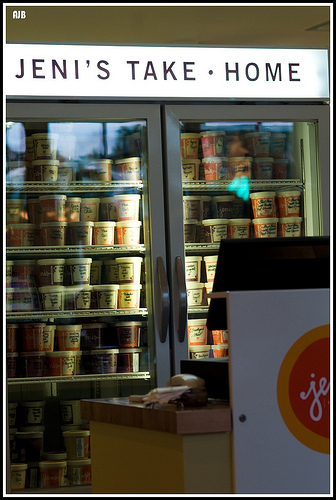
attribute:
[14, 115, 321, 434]
display — ice cream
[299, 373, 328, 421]
letters — white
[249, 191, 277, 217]
container — ice cream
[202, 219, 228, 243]
container — ice cream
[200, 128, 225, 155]
container — ice cream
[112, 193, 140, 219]
container — ice cream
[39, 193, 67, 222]
container — ice cream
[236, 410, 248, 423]
screw — small, black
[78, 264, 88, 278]
lettering — Black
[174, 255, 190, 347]
door handle — silver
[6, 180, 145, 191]
rack — white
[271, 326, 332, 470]
circle — yellow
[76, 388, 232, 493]
counter — Wood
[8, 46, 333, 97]
sign — white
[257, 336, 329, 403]
logo — Red, orange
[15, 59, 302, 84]
letter — Black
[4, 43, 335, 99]
sign — Lighted, white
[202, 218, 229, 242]
container — Brown, white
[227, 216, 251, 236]
container — Brown, white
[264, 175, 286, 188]
rack — white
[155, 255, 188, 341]
handles — Metal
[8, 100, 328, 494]
glass doors — Clear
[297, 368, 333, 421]
writing — White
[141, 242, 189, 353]
handles — metal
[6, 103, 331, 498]
case — glass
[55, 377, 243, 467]
counter top — wooden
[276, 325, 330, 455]
background — orange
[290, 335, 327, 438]
circle — orange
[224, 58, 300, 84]
word — Black lettered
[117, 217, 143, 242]
container — many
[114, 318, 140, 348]
container — many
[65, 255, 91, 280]
container — many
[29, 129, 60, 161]
container — many